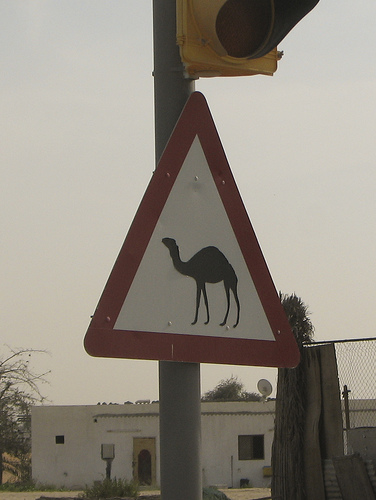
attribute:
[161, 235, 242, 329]
camel — black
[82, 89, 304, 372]
sign — triangle, red white, black, red, white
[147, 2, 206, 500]
pole — metal, gray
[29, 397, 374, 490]
building — white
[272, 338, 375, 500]
fence — chain link, metal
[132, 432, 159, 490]
door — yellow, tan, closed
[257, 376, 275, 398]
satellite dish — round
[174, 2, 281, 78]
casing — yellow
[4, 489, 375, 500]
sand — beige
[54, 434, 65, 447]
square — black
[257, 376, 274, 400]
antenna — white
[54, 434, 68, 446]
opening — square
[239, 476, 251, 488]
animal — dark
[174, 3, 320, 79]
signal — yellow